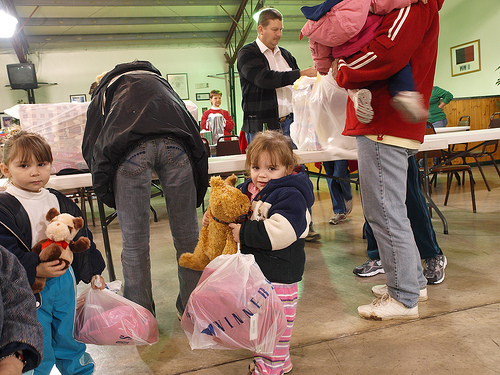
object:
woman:
[77, 56, 220, 320]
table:
[3, 141, 453, 204]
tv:
[5, 61, 38, 85]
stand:
[3, 82, 58, 104]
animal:
[30, 207, 91, 295]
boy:
[200, 89, 235, 145]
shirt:
[200, 106, 235, 144]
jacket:
[335, 0, 446, 144]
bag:
[179, 253, 287, 356]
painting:
[449, 39, 482, 78]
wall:
[433, 2, 499, 95]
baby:
[201, 129, 315, 375]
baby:
[0, 129, 105, 375]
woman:
[197, 90, 239, 147]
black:
[243, 56, 259, 118]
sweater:
[236, 40, 300, 120]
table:
[418, 126, 500, 234]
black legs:
[96, 197, 118, 282]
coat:
[235, 165, 315, 285]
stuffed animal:
[177, 173, 252, 272]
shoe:
[355, 291, 420, 321]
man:
[235, 7, 318, 150]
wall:
[438, 1, 498, 121]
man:
[330, 0, 441, 321]